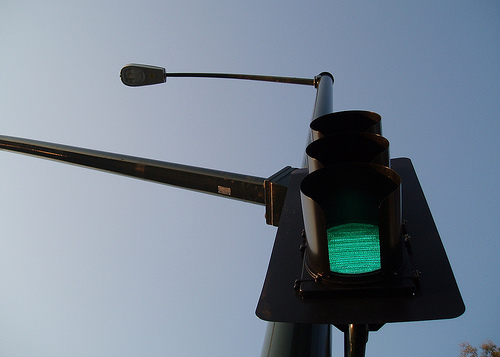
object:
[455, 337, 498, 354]
leaves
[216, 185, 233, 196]
sticker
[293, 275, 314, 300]
bolt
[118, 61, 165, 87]
lamp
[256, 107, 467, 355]
light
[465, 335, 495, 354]
tree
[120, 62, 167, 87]
bulb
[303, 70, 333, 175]
metal pole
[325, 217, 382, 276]
bulb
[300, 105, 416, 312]
traffic light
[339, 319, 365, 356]
pole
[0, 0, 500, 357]
blue sky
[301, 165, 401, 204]
cover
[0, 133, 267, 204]
arm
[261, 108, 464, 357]
traffic signal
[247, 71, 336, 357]
pole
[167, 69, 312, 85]
arm